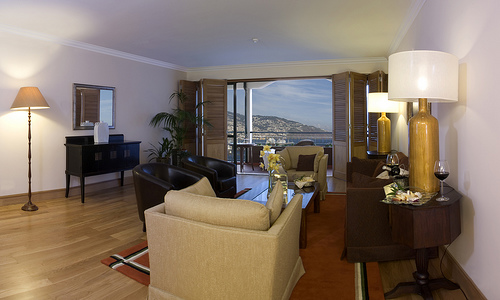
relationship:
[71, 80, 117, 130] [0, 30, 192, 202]
mirror on wall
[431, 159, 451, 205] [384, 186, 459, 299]
glass on endtable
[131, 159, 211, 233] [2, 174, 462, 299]
chair on floor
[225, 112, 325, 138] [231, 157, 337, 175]
mountain near balcony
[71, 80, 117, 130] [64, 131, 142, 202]
mirror above cabinet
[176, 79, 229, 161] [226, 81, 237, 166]
shutter by door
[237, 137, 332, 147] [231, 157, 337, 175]
lake seen from balcony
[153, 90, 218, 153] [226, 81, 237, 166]
plant by door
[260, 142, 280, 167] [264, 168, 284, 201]
flower in vase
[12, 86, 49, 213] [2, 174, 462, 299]
light on floor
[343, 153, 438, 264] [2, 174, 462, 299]
sofa on floor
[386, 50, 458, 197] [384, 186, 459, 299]
lamp on endtable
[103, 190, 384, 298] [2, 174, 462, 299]
rug on floor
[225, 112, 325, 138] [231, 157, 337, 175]
mountain from balcony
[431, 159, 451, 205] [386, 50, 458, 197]
glass by lamp